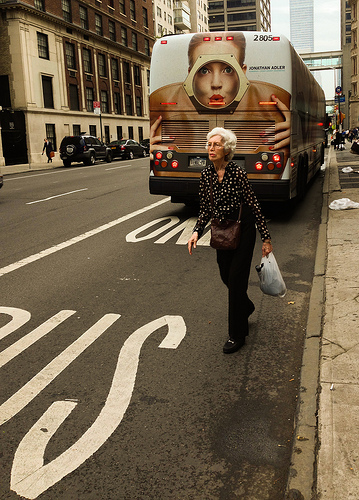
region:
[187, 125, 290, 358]
Woman walking carrying a white bag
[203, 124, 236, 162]
Woman with white hair and glasses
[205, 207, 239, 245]
Woman carrying a brown purse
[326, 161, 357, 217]
Trash on the sidewalk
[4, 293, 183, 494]
White letters painted on the street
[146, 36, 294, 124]
Picture of a lady on back of a bus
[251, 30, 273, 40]
Black numbers on white bus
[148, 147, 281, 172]
Rear brake lights on the bus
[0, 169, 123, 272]
White lines painted on the road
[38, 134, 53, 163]
Man walking down the sidewalk carrying a bag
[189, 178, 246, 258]
woman carring a brown purse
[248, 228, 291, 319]
a woman carrying a plastic bag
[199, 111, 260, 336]
a woman walking on a street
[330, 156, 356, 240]
bags littering the sidewalk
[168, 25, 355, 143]
a bus stopped near a sidewalk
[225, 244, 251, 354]
a woman wearing black pants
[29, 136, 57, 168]
a person walking near a building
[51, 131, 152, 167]
cars parked near a building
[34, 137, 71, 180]
a person walking on a sidewalk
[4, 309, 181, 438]
letters painted on the street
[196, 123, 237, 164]
woman with gray hair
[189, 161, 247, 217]
woman wearing a black and white shirt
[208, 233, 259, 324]
woman wearing black pants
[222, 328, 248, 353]
woman wearing black shoes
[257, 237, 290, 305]
woman carrying a plastic bag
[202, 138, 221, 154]
woman wearing reading glasses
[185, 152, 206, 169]
license on a bus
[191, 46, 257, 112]
picture on a bus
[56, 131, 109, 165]
car parked on a street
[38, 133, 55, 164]
man walking on the street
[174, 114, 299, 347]
old woman crossing the street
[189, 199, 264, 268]
the bag is brown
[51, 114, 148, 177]
the cars are parked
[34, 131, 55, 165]
a man walking at the sidewalk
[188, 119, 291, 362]
This is a person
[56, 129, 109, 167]
This is a car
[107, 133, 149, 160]
This is a car